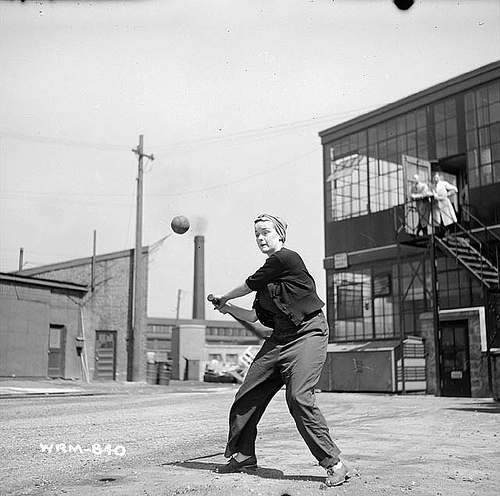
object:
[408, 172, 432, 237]
men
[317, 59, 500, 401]
building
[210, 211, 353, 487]
woman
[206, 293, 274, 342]
bat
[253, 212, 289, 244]
bandana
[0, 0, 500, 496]
photo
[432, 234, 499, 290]
ladder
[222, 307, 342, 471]
pants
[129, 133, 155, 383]
electrical pole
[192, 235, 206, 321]
smokestack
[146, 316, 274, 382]
building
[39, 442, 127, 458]
wrm-840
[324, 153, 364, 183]
window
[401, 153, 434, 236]
door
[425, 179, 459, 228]
coat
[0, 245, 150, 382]
building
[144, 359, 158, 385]
barrels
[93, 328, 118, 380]
door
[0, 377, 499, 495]
parking lot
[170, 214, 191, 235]
ball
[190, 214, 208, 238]
smoke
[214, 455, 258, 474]
shoe